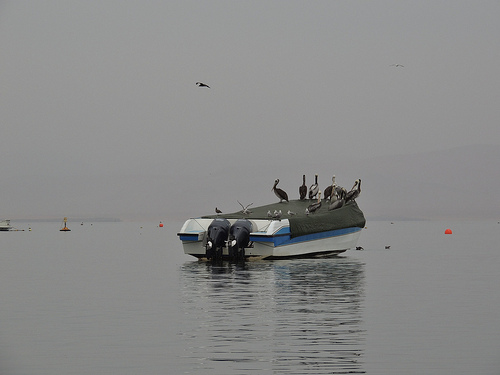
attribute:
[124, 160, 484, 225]
fog-covered hill — covered, fog covered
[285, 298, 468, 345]
water — calm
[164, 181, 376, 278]
boat — covered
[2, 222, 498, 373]
water — calm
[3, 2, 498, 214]
sky — hazy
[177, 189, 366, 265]
boat — covered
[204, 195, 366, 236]
cover — black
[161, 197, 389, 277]
boat — blue, white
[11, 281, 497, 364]
surface — water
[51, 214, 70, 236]
buoy — tall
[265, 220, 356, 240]
stripe — blue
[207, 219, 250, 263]
motor — black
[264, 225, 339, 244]
stripe — blue